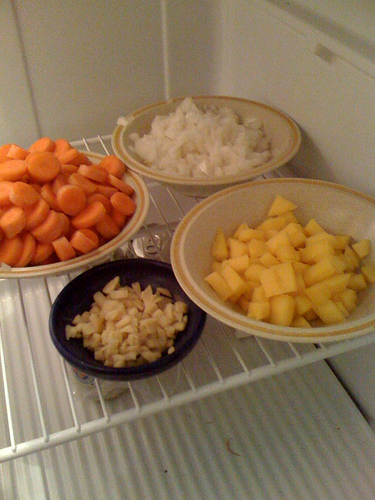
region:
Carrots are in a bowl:
[0, 135, 148, 278]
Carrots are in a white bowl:
[0, 136, 150, 281]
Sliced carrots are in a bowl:
[0, 132, 150, 279]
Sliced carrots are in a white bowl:
[0, 136, 150, 279]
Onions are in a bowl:
[111, 93, 313, 199]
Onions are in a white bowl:
[108, 90, 303, 198]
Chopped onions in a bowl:
[110, 92, 305, 198]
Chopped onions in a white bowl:
[108, 92, 305, 199]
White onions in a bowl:
[111, 92, 306, 200]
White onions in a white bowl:
[111, 95, 304, 199]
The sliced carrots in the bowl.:
[2, 139, 127, 252]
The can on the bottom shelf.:
[136, 224, 177, 260]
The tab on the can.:
[145, 233, 159, 252]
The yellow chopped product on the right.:
[227, 188, 358, 321]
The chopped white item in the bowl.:
[138, 101, 264, 166]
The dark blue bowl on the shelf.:
[48, 256, 204, 378]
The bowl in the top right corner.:
[110, 89, 302, 179]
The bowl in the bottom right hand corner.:
[170, 175, 374, 335]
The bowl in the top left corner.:
[4, 135, 152, 268]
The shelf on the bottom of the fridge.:
[0, 270, 370, 496]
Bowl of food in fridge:
[120, 82, 303, 180]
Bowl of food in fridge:
[180, 178, 358, 370]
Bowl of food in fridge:
[41, 274, 190, 401]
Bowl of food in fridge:
[5, 127, 161, 252]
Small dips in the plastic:
[302, 415, 334, 478]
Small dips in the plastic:
[275, 405, 318, 441]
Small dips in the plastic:
[222, 419, 274, 457]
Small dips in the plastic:
[180, 435, 237, 469]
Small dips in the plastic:
[140, 441, 206, 476]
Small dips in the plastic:
[51, 452, 138, 498]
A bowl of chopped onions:
[109, 72, 301, 191]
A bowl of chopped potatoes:
[186, 175, 373, 340]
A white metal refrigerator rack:
[4, 286, 45, 454]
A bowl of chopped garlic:
[40, 256, 215, 379]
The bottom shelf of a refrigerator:
[245, 390, 346, 492]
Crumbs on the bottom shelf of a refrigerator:
[221, 427, 246, 467]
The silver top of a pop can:
[126, 223, 181, 263]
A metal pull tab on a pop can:
[141, 231, 165, 258]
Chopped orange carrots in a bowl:
[0, 114, 156, 288]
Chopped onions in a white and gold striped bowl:
[100, 83, 333, 190]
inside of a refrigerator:
[2, 8, 370, 497]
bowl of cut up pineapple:
[178, 185, 374, 341]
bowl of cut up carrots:
[113, 99, 315, 186]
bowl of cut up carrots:
[0, 139, 149, 269]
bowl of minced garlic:
[49, 259, 204, 384]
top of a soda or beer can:
[133, 221, 172, 261]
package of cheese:
[77, 371, 125, 399]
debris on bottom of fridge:
[223, 430, 236, 465]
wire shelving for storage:
[4, 269, 373, 451]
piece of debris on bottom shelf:
[158, 464, 171, 479]